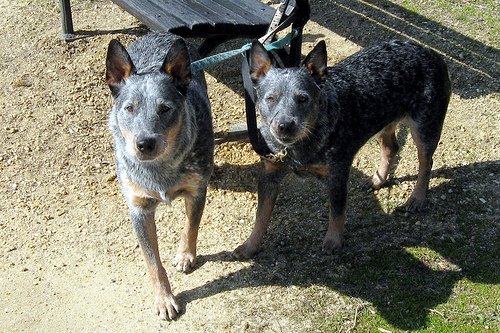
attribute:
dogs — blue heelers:
[99, 42, 471, 329]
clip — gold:
[265, 144, 284, 163]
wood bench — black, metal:
[107, 0, 289, 37]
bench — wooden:
[47, 1, 326, 168]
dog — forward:
[103, 20, 227, 316]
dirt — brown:
[2, 2, 484, 330]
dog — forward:
[246, 32, 443, 252]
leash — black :
[240, 0, 309, 164]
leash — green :
[180, 32, 302, 63]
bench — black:
[57, 0, 309, 82]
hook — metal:
[262, 147, 290, 162]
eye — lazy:
[242, 81, 347, 127]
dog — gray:
[98, 25, 224, 330]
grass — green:
[391, 276, 453, 323]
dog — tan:
[129, 187, 149, 210]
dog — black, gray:
[103, 33, 211, 320]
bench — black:
[53, 0, 334, 46]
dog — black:
[229, 38, 453, 266]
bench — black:
[52, 0, 312, 142]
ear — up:
[245, 37, 279, 91]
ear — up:
[301, 37, 332, 85]